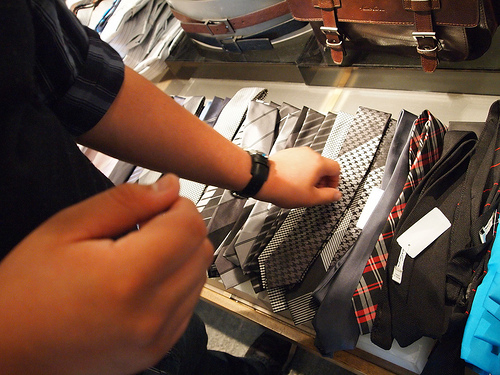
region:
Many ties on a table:
[150, 56, 453, 334]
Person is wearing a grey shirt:
[17, 11, 198, 304]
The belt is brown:
[168, 3, 312, 50]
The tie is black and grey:
[255, 112, 392, 289]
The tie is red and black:
[349, 113, 456, 332]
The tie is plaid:
[345, 110, 445, 331]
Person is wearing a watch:
[197, 131, 292, 201]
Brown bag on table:
[285, 1, 480, 81]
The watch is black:
[223, 130, 285, 212]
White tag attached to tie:
[388, 191, 456, 277]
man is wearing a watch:
[216, 122, 294, 200]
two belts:
[171, 1, 303, 66]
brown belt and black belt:
[161, 5, 328, 57]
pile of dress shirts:
[100, 10, 192, 71]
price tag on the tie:
[405, 210, 438, 275]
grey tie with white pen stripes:
[278, 106, 373, 151]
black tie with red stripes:
[475, 178, 492, 219]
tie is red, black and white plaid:
[382, 135, 422, 285]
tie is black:
[398, 152, 439, 342]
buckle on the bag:
[317, 18, 374, 72]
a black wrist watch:
[229, 148, 271, 203]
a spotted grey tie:
[262, 106, 389, 291]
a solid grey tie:
[302, 110, 419, 353]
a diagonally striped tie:
[231, 108, 324, 297]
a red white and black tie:
[340, 111, 442, 338]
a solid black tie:
[368, 121, 482, 346]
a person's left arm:
[68, 62, 353, 212]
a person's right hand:
[8, 166, 222, 373]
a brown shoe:
[231, 325, 298, 367]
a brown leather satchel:
[283, 0, 493, 62]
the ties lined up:
[152, 86, 499, 311]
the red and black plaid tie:
[355, 112, 431, 339]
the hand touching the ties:
[265, 131, 345, 207]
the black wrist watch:
[231, 146, 268, 201]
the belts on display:
[169, 2, 299, 54]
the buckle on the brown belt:
[202, 17, 232, 37]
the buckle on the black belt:
[220, 32, 244, 54]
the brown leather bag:
[290, 1, 499, 68]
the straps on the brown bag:
[317, 1, 438, 73]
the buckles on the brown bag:
[321, 22, 443, 56]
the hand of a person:
[254, 133, 346, 213]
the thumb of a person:
[45, 170, 187, 249]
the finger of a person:
[117, 191, 209, 286]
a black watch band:
[223, 145, 275, 203]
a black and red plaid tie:
[338, 110, 450, 337]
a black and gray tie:
[256, 102, 395, 294]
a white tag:
[393, 202, 455, 262]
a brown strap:
[313, 0, 348, 73]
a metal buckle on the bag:
[408, 26, 446, 62]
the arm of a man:
[0, 1, 259, 195]